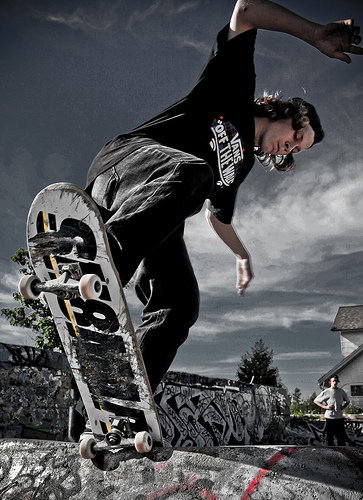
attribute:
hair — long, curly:
[255, 98, 312, 135]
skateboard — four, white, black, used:
[23, 199, 153, 462]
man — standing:
[324, 379, 356, 440]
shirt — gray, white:
[324, 389, 342, 419]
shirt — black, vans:
[101, 80, 272, 207]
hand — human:
[233, 261, 254, 292]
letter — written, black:
[60, 340, 130, 374]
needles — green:
[249, 346, 273, 358]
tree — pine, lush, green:
[237, 335, 296, 387]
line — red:
[247, 442, 283, 494]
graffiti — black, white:
[166, 382, 274, 439]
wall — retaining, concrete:
[24, 340, 329, 446]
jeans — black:
[324, 421, 358, 447]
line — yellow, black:
[57, 287, 91, 350]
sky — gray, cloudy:
[17, 21, 201, 111]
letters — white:
[213, 108, 241, 201]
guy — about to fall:
[137, 9, 299, 305]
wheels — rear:
[61, 415, 170, 469]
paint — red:
[256, 454, 298, 490]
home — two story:
[319, 298, 357, 394]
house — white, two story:
[319, 291, 360, 403]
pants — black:
[321, 416, 353, 449]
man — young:
[83, 55, 302, 307]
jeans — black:
[98, 175, 187, 365]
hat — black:
[292, 77, 321, 145]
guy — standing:
[314, 372, 360, 446]